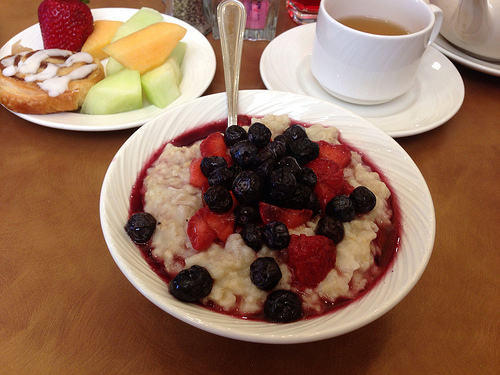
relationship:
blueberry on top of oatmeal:
[200, 151, 222, 183] [164, 144, 383, 293]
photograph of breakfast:
[2, 5, 485, 373] [31, 11, 486, 367]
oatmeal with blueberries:
[123, 113, 404, 325] [111, 117, 390, 333]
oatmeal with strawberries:
[123, 113, 404, 325] [182, 122, 367, 292]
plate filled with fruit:
[0, 5, 216, 130] [87, 9, 193, 113]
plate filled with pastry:
[0, 5, 216, 130] [0, 48, 104, 113]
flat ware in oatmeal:
[214, 0, 247, 129] [136, 110, 401, 319]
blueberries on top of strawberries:
[218, 122, 321, 226] [317, 134, 356, 196]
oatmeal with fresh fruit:
[211, 249, 242, 282] [0, 0, 187, 115]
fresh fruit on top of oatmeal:
[0, 0, 187, 115] [211, 249, 242, 282]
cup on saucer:
[311, 0, 443, 106] [259, 22, 470, 139]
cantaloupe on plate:
[102, 21, 187, 75] [0, 5, 216, 130]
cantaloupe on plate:
[109, 15, 179, 73] [0, 5, 216, 130]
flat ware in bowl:
[198, 2, 260, 147] [72, 57, 499, 357]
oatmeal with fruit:
[123, 113, 404, 325] [220, 127, 314, 248]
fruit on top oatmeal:
[220, 127, 314, 248] [123, 113, 404, 325]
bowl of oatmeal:
[93, 83, 441, 337] [136, 110, 401, 319]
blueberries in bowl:
[224, 147, 254, 161] [93, 83, 441, 337]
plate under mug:
[255, 22, 472, 138] [312, 1, 441, 106]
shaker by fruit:
[156, 0, 221, 48] [106, 6, 184, 75]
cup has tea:
[311, 0, 443, 106] [336, 9, 416, 40]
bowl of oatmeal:
[93, 83, 441, 337] [123, 113, 404, 325]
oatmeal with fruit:
[123, 113, 404, 325] [282, 126, 362, 202]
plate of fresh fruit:
[0, 5, 216, 130] [35, 0, 189, 112]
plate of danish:
[0, 5, 216, 130] [0, 37, 107, 109]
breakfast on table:
[0, 0, 466, 346] [2, 8, 498, 369]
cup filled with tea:
[311, 0, 443, 106] [333, 12, 412, 38]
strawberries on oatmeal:
[309, 143, 356, 194] [147, 168, 183, 203]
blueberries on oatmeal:
[211, 143, 302, 186] [147, 168, 183, 203]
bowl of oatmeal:
[93, 83, 441, 337] [145, 115, 390, 312]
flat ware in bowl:
[214, 0, 247, 129] [93, 83, 441, 337]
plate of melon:
[0, 5, 216, 130] [101, 22, 188, 72]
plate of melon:
[0, 5, 216, 130] [81, 69, 146, 111]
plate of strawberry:
[0, 5, 216, 130] [36, 0, 92, 55]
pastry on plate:
[0, 43, 105, 117] [0, 5, 216, 130]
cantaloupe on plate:
[108, 6, 163, 44] [0, 5, 216, 130]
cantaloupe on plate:
[140, 63, 180, 109] [0, 5, 216, 130]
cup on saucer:
[308, 2, 448, 101] [259, 22, 470, 139]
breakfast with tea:
[1, 0, 398, 329] [333, 16, 409, 34]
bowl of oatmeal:
[93, 83, 441, 337] [149, 125, 377, 312]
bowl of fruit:
[93, 83, 441, 337] [187, 124, 352, 285]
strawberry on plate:
[36, 0, 93, 50] [0, 5, 216, 130]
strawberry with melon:
[36, 0, 93, 50] [86, 11, 190, 114]